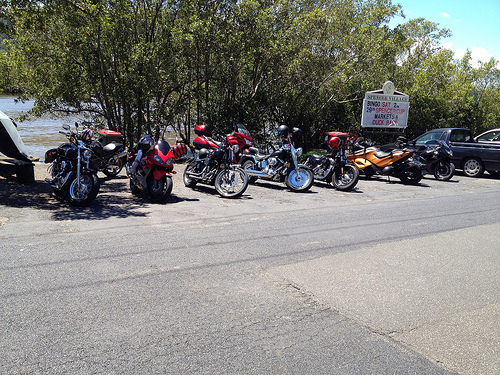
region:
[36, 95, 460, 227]
Several motorcycles are together.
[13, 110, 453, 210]
The motorcycles are in a row.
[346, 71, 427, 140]
A sign is behind the motorcycles.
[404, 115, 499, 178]
A truck is next to the motorcycles.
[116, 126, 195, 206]
The motorcycle is red.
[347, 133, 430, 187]
The motorcycle is orange.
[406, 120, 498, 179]
The truck is blue.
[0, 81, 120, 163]
Water is behind the parking lot.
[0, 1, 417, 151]
Trees are behind the motorcycles.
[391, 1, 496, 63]
The sky is blue.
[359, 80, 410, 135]
sign reading spencer village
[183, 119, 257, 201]
red and black motorcycle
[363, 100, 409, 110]
bingo saturday at 2pm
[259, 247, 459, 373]
long crack in pavement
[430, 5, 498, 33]
aqua sky with puffy little cloud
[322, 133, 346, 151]
helmet hooked on handlebar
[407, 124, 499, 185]
black pick up truck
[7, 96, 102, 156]
murky river water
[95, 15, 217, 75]
green leaves on trees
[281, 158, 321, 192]
shiny chrome wheel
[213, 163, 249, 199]
Black tire on motorcycle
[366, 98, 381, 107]
Black letters on sign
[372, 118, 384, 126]
Red letters on sign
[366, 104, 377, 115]
Blue letters on sign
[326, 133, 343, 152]
Red helmet on bike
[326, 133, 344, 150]
Round red helmet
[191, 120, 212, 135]
Storage container on bike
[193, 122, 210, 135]
Red storage container on bike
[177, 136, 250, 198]
Black motorcycle on concrete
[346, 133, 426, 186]
Bright motorcycle near sign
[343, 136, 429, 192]
golden cafe racer, nicer than most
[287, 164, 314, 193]
solid silvertone hubcap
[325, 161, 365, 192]
hubcap w/ silvertone skull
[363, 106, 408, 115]
'29th spencer cup'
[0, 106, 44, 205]
a tent in the parking lot? white, & w/ a camp bench before it? w/ a khaki blanket on?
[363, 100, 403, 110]
'bingo sat 2pm' in black+red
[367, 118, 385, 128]
'duck' in red [the word after i dont know & dont wanna know]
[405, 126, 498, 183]
black pickup, fancy hubcaps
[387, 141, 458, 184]
blue cafe racer @ far end, more typical than the goldtone one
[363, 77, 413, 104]
something that starts w/ 'm' 'terrace' beneath an oval upstanding logo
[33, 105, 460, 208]
seven motorcycles parked on side of street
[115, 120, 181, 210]
front of motorcycle is red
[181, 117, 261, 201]
motorcycle is red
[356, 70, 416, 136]
a sign next to trees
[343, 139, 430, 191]
a yellow motorcycle with black sit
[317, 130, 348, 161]
a red helmet hang from a motorcycle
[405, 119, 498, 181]
a black truck next to motorcycles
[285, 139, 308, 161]
headlight of motorcycle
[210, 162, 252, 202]
front tire of motorcycle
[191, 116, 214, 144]
red and black bow behind a motorcycle